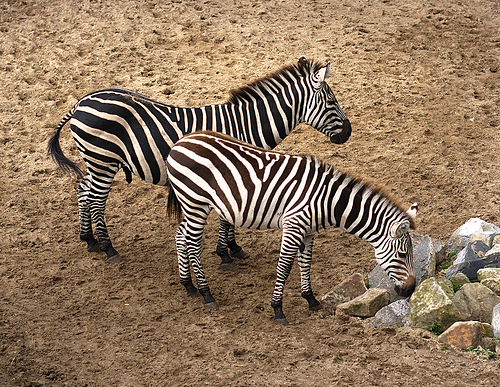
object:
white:
[255, 180, 262, 189]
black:
[242, 169, 248, 177]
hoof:
[309, 304, 323, 311]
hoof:
[274, 318, 288, 325]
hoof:
[205, 301, 220, 309]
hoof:
[221, 262, 238, 270]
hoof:
[233, 249, 250, 258]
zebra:
[45, 56, 351, 263]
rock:
[437, 320, 494, 348]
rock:
[446, 217, 500, 281]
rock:
[476, 267, 500, 294]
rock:
[335, 288, 390, 317]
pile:
[321, 218, 499, 353]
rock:
[369, 235, 438, 302]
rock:
[321, 272, 367, 307]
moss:
[433, 276, 454, 298]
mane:
[228, 59, 324, 104]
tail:
[46, 102, 86, 178]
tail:
[166, 180, 182, 224]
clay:
[388, 115, 483, 174]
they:
[48, 56, 419, 327]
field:
[2, 0, 499, 385]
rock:
[409, 276, 469, 332]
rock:
[373, 299, 409, 327]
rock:
[451, 281, 500, 322]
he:
[166, 131, 418, 325]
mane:
[341, 167, 417, 230]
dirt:
[0, 0, 500, 387]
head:
[369, 201, 423, 297]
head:
[294, 55, 353, 143]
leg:
[269, 222, 304, 304]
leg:
[297, 233, 314, 294]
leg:
[175, 217, 193, 282]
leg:
[181, 202, 212, 290]